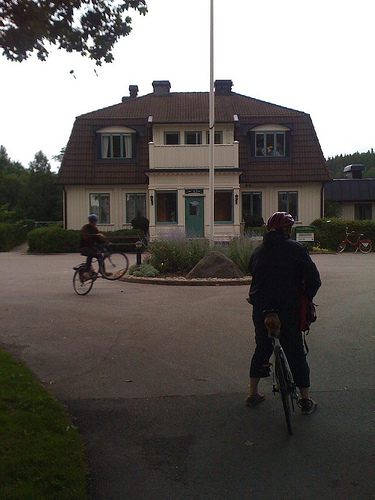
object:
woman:
[245, 208, 320, 416]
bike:
[263, 311, 312, 439]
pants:
[249, 300, 309, 386]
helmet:
[266, 212, 297, 237]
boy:
[77, 212, 113, 282]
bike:
[71, 248, 131, 294]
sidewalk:
[0, 249, 375, 500]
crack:
[56, 386, 374, 400]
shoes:
[297, 397, 318, 414]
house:
[56, 77, 330, 252]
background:
[0, 0, 375, 500]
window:
[153, 189, 177, 227]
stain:
[142, 429, 203, 485]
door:
[183, 191, 207, 236]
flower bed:
[113, 224, 276, 287]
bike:
[333, 216, 371, 250]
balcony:
[145, 125, 241, 174]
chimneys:
[151, 80, 170, 98]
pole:
[205, 0, 216, 256]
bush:
[25, 223, 147, 253]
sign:
[135, 239, 144, 266]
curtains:
[122, 133, 134, 159]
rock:
[188, 252, 246, 279]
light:
[233, 113, 239, 122]